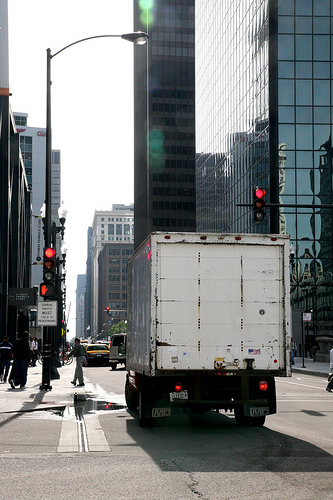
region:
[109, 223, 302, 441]
back of a white and black delivery van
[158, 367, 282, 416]
rear brake lights and turn signals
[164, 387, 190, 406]
license plate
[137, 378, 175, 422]
mud flap with white logo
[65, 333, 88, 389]
pedestrian wearing khaki pants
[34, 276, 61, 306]
pedestrian cross walk signal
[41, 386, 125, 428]
puddle on a city street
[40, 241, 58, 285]
traffic signal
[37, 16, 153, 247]
street lamp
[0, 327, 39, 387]
pedestrians walking on the sidewalk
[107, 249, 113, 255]
a window on a building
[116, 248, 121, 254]
a window on a building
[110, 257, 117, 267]
a window on a building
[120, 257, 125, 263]
a window on a building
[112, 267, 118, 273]
a window on a building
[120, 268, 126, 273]
a window on a building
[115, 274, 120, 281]
a window on a building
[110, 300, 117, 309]
a window on a building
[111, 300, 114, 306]
a window on a building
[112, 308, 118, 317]
a window on a building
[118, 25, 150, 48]
tall street unlit lamp high above white boxed truck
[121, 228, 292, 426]
white boxed truck passing thru a red light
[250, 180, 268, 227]
stop light lit up red above the box truck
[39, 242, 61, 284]
street light lit up red to the left of the boxed truck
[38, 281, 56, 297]
walk light lit up red telling walkers not to walk under the red light to the left of the boxed truck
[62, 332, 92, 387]
man at the edge of sidewalk in grey shirt and pants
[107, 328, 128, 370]
white van veering into traffic in front of the white boxed truck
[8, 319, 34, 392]
person dressed in what looks like a black robe on sidewalk passing the street light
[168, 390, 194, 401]
license plate of the white boxed truck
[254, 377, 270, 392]
right tail light of the boxed truck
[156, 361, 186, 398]
Red light on truck.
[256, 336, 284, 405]
Red light on truck.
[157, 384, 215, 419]
White license plate on truck.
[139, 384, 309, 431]
Black bottom on truck.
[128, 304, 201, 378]
White box truck on road.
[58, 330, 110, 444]
Man walking on side of street.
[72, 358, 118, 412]
Man wearing tan pants.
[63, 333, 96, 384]
Man wearing green shirt.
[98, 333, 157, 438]
White van in front of truck.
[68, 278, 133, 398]
Large buildings in background.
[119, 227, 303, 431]
Old white delivery truck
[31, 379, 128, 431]
Puddle of water in street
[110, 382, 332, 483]
Shadow cast by truck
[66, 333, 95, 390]
Male pedestrian on the sidewalk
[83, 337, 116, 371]
black and yellow taxi cab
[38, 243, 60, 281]
The traffic light is red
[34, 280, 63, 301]
Do not walk signal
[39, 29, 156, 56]
The streetlight is off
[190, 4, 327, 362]
The glass building is tall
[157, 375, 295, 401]
The brake lights are red